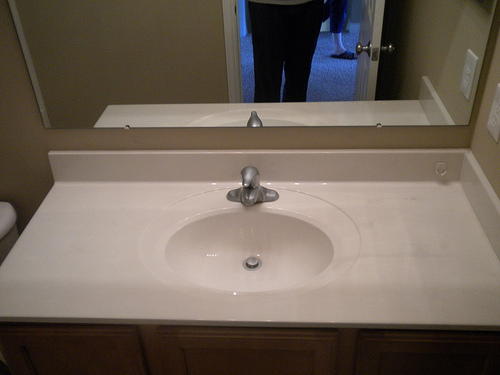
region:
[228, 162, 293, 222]
this is a tap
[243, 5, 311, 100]
this is a person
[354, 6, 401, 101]
this is a door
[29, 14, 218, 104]
this is a wall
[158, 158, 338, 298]
Silver faucet over a sink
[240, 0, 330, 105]
Person's reflection in the mirror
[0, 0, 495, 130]
A mirror hanging on the wall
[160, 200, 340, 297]
The sink is oval shaped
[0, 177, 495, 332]
The countertop is white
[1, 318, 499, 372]
Brown and wooden cabinets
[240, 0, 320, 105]
Person wearing black pants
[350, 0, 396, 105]
A white door is wide open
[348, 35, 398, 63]
Two doorknobs on the door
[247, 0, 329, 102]
reflection of person in the mirror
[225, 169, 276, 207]
silver faucet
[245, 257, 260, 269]
silver sink stopper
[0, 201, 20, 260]
part of toilet can be seen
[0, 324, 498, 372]
wooden, tan cabinets under the counter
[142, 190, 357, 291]
white, shiny sink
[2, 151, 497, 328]
a white bathroom counter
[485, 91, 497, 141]
a white electric socket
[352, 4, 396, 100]
reflection of the door in the mirror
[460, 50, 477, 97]
electric socket reflected through the mirror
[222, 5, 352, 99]
someones reflection in the mirror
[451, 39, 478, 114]
reflection of a wall outlet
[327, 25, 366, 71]
someones foot in the reflection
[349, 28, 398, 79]
door knob in he reflection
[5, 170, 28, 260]
top of the toilet bowl lid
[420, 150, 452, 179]
a hook on the top of a sink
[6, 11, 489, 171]
mirror on the top of a sink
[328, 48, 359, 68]
slippers in the mirror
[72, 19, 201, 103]
reflection of the wall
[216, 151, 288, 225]
This is a water tap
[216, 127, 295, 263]
This is a water tap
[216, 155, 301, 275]
This is a water tap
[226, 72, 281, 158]
This is a water tap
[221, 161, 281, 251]
This is a water tap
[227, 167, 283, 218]
This is a water tap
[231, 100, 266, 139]
This is a water tap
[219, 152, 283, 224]
This is a water tap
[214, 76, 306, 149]
This is a water tap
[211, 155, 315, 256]
This is a water tap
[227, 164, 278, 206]
A silver faucet.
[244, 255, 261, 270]
A silver sink drain.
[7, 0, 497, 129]
A mirror over the sink.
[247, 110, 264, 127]
A silver faucet in the mirror.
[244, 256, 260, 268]
Silver sink drain.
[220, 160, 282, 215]
silver faucet on sink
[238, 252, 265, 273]
silver drain at bottom of sink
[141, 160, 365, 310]
white sink in bathroom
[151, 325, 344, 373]
top of brown cabinet door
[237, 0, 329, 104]
reflection of person's pants in mirror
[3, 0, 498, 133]
mirror in front of sink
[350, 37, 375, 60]
metal door knob on bathroom door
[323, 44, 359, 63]
house slipper on person's foot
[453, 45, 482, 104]
white electric outlet on wall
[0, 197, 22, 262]
top edge of white toilet tank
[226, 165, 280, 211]
a silver sink faucet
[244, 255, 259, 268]
a silver sink drain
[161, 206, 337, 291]
white porcelain sink basin